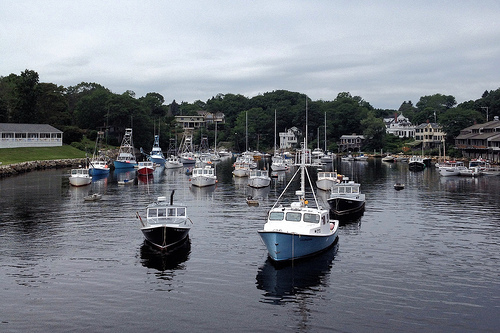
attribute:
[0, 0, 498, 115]
clouds — white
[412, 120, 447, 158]
house — large, tan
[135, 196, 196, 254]
boat — small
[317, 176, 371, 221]
boat — small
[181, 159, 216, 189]
boat — small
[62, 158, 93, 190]
boat — small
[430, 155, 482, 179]
boat — small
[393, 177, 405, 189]
boat — small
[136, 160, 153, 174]
boat — small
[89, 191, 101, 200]
boat — small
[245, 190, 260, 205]
boat — small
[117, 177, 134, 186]
boat — small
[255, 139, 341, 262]
boat — blue, white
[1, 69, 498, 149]
trees — large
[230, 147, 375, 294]
boat — small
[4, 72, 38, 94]
leaves — green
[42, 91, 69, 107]
leaves — green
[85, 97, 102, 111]
leaves — green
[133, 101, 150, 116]
leaves — green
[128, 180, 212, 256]
boat — small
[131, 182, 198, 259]
boat — black, grey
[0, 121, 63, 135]
roof — grey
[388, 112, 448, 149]
house — white, large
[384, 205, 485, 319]
water — calm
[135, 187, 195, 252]
boat — small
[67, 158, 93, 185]
boat — small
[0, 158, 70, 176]
wall — concrete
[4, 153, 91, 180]
bank — rock